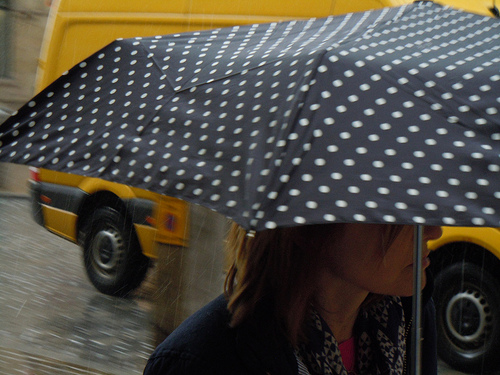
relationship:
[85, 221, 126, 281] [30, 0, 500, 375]
rim of car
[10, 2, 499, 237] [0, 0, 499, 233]
umbrella with polka dots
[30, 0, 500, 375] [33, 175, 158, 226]
car with trim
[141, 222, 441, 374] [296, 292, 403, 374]
person wearing scarf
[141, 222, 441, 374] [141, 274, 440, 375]
person wearing coat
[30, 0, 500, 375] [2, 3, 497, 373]
car on street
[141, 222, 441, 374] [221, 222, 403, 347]
person with hair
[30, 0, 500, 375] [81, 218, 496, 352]
car with gray rims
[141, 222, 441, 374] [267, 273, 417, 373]
person wearing scarf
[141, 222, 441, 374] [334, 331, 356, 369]
person wearing shirt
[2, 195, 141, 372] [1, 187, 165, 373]
water on asphalt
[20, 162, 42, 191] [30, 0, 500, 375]
reflector on car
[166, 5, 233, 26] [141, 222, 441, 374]
car beside person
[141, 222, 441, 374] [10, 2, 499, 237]
person holding umbrella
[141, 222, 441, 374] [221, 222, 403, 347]
person has hair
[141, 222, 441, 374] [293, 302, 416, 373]
person wearing scarf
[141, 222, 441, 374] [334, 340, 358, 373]
person wearing pink shirt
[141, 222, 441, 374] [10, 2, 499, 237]
person under umbrella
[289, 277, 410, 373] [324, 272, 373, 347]
scarf on neck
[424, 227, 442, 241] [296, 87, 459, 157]
woman's nose under umbrella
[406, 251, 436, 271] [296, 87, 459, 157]
lips under umbrella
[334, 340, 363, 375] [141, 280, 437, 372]
pink shirt of coat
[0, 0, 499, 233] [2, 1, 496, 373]
polka dots on umbrella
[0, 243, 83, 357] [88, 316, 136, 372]
rain falling to ground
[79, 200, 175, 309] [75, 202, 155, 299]
tire on tire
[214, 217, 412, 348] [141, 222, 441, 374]
hair on person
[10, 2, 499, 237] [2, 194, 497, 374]
umbrella on street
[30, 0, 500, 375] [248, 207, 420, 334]
car behind woman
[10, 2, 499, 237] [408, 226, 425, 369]
umbrella on post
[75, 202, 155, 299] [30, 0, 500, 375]
tire of car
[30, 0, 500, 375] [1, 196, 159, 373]
car on street